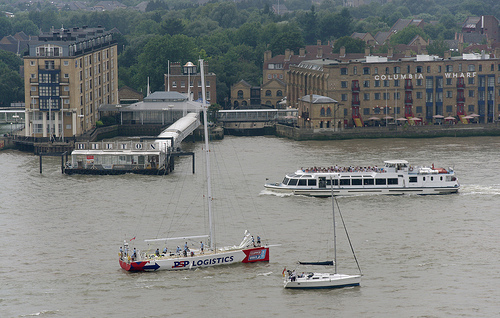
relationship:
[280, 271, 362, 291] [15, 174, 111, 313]
boat in water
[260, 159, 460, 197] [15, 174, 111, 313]
boat in water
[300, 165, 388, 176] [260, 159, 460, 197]
people on boat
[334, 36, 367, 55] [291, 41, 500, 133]
tree behind building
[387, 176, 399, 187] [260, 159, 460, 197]
window on boat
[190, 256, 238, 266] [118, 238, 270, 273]
logistics on boat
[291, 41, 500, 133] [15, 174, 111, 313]
building behind water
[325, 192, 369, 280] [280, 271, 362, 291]
sail on boat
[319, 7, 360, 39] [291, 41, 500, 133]
tree behind building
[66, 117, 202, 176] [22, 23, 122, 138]
docking for hotel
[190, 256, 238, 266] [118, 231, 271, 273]
logistics on boat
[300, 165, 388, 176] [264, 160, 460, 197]
people on boat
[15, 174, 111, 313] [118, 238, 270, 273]
water holding boat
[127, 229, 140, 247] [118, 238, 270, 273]
flag on boat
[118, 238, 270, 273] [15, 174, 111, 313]
boat in water